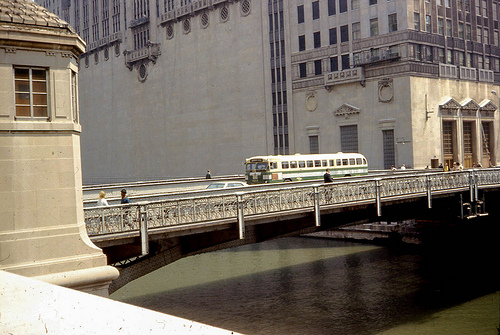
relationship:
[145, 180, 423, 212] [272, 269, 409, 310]
bridge over water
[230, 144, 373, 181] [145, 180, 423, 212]
bus crossing bridge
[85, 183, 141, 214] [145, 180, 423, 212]
two people walking on bridge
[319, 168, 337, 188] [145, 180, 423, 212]
man crossing bridge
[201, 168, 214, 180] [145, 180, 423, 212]
person crossing bridge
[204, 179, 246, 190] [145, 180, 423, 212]
car driving across bridge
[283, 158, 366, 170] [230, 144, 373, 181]
windows on bus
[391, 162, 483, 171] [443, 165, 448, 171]
people wearing a shirt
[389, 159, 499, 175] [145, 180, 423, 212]
people walking across bridge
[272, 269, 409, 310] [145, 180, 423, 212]
water under bridge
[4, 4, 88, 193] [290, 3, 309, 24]
building has a window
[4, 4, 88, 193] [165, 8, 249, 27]
building has designs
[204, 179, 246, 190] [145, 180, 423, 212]
car crossing bridge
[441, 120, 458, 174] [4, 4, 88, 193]
door in front of building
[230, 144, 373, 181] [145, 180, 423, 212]
bus going over bridge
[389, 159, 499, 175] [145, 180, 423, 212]
people going over bridge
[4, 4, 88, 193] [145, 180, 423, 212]
building near bridge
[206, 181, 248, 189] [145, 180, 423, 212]
car going over bridge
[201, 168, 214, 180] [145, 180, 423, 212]
person walking on a bridge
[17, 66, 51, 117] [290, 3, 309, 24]
eight panes on window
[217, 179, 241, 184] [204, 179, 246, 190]
top of a car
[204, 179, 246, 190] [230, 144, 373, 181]
car in front of bus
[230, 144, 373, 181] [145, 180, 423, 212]
bus on a bridge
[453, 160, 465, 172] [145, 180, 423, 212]
brunette walking on a bridge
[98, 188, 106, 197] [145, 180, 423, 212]
blonde walking on a bridge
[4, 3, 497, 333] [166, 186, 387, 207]
photograph of a small city bridge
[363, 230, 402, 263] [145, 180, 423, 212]
shadow of a bridge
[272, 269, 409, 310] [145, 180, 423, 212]
water below bridge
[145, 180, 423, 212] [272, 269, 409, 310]
bridge built over water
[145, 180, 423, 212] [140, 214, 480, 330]
bridge over water